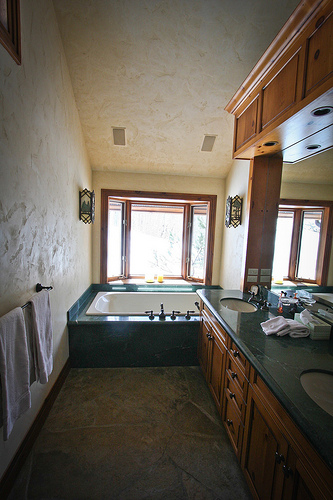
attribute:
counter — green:
[192, 287, 331, 459]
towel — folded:
[296, 305, 329, 342]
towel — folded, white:
[279, 316, 306, 344]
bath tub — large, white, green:
[86, 287, 202, 319]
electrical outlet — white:
[245, 269, 257, 285]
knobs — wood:
[267, 451, 284, 465]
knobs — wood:
[282, 465, 302, 482]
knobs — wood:
[224, 364, 239, 383]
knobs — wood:
[224, 389, 240, 406]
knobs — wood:
[220, 418, 238, 432]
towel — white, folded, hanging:
[25, 287, 55, 389]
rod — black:
[0, 281, 56, 320]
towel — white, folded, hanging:
[0, 304, 36, 441]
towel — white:
[259, 316, 286, 341]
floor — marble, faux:
[6, 362, 254, 498]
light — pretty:
[78, 184, 97, 228]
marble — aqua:
[66, 281, 206, 369]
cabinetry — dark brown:
[231, 5, 331, 154]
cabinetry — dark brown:
[195, 309, 230, 414]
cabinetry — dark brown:
[242, 385, 314, 498]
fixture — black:
[33, 283, 59, 297]